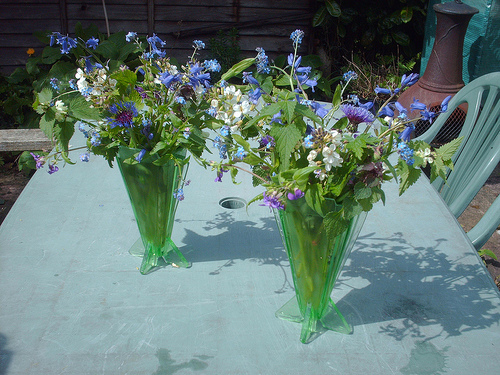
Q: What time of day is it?
A: Daytime.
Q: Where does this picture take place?
A: Outside at a table.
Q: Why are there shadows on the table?
A: The shadow is a reflection of the flowers and vases.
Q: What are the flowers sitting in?
A: Vases.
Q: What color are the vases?
A: Green.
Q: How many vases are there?
A: Two.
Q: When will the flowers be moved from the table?
A: When the sun goes down.